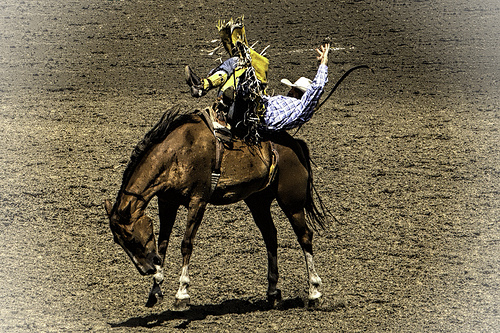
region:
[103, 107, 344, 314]
Bucking bronco with its feet in the air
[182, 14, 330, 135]
Cowboy being thrown about by a bucking horse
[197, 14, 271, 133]
Yellow chaps with fringe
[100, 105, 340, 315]
A brown horse with white on each leg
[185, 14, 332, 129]
A cowboy wearing chaps and a hat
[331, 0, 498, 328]
A pin filled with a smooth layer of dirt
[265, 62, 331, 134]
Blue flannel long-sleeved shirt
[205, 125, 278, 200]
Two straps holding a saddle onto a horse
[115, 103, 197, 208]
Brown horse mane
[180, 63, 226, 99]
One yellow cowboy boot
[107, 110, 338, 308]
a brown and black rodeo horse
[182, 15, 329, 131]
a colorfully dressed rodeo rider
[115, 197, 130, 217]
A horse's left ear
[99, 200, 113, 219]
A horse's right ear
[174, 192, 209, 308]
A horse's left front leg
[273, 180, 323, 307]
A horse's left rear leg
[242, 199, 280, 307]
A horse's right rear leg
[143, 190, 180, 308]
A horse's right front leg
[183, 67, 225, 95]
A cowboy's leather boot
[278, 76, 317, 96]
A cowboy's white hat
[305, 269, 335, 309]
hoof of the horse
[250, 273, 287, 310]
hoof of the horse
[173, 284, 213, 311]
hoof of hte horse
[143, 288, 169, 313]
hoof of the horse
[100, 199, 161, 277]
head of the horse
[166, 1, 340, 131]
cowboy on the horse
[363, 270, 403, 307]
dirt in the arena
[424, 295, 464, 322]
dirt in the arena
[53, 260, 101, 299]
dirt in the arena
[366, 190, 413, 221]
dirt in the arena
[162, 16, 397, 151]
cowboy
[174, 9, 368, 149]
cowboy wearing a hat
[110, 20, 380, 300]
cowboy on a horse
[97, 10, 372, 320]
man on a horse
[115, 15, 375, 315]
horse trying to throw a man off its back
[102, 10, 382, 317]
horse trying to throw a cowboy off its back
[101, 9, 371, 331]
cowboy in a checkered shirt being thrown off a horse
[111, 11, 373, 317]
man in a hat being thrown off a horse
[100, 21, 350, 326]
brown horse trying to throw a man off his back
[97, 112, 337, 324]
brown horse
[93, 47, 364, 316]
Man on a horse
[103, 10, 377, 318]
Man is on a horse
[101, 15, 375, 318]
Man on a brown horse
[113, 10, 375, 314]
Man is on a brown horse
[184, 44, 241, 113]
Man wearing shoes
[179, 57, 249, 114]
Man is wearing shoes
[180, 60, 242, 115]
Man wearing boots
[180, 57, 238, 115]
Man is wearing boots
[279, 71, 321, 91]
Man wearing a cowboy hat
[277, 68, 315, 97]
Man is wearing a white cowboy hat